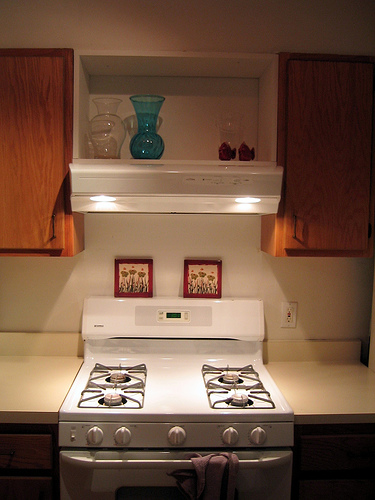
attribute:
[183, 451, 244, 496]
towel — hanging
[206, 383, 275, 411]
burner — bottom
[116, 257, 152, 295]
picture — identical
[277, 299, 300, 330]
electrical outlet — white 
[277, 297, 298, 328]
outlet — white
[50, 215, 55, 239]
handle — black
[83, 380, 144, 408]
burner — bottom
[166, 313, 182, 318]
readout — digital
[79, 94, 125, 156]
vase — clear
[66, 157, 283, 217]
shelf — white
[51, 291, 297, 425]
stove — white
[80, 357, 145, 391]
burner — top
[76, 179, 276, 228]
lights — white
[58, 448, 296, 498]
door — white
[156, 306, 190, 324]
display — digital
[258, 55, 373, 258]
cabinet — brown, wooden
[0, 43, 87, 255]
cabinet — brown, wooden